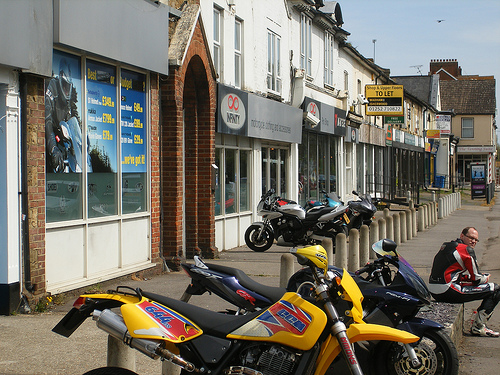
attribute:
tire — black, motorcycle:
[385, 316, 459, 373]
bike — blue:
[419, 239, 435, 331]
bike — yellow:
[51, 240, 429, 373]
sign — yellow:
[360, 85, 415, 123]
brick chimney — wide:
[430, 57, 462, 78]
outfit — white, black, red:
[425, 239, 498, 341]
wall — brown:
[449, 112, 494, 152]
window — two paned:
[459, 116, 473, 138]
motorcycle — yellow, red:
[69, 250, 444, 371]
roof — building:
[396, 48, 473, 97]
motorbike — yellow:
[41, 242, 422, 374]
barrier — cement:
[278, 254, 298, 293]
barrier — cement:
[334, 230, 349, 272]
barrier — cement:
[349, 225, 361, 269]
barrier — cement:
[368, 220, 381, 257]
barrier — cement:
[402, 207, 409, 241]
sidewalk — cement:
[11, 197, 438, 374]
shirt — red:
[427, 233, 485, 288]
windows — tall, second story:
[294, 9, 344, 89]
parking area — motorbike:
[56, 180, 498, 372]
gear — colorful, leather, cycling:
[434, 235, 494, 315]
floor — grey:
[5, 319, 59, 366]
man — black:
[423, 222, 498, 339]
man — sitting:
[410, 206, 491, 303]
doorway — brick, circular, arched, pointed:
[163, 3, 218, 268]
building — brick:
[2, 1, 305, 270]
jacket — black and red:
[428, 240, 490, 286]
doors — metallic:
[53, 174, 155, 283]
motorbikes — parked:
[240, 176, 395, 253]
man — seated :
[407, 234, 489, 296]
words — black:
[124, 117, 145, 134]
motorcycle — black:
[176, 236, 457, 373]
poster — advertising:
[44, 51, 150, 176]